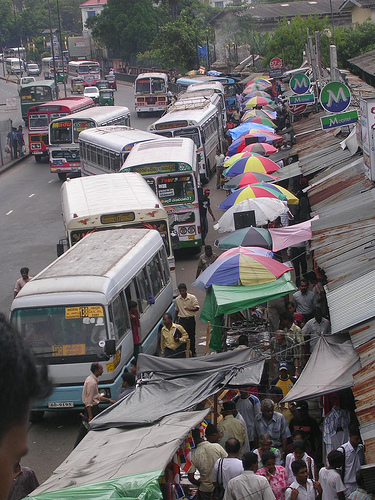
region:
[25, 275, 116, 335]
bus on a street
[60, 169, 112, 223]
bus on a street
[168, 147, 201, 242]
bus on a street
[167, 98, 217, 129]
bus on a street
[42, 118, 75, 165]
bus on a street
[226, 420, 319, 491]
people on a street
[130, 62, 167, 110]
bus on a street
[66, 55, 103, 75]
bus on a street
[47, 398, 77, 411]
plate on a bus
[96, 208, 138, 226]
sign on a bus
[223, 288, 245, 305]
the tarp is green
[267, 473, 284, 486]
the shirt is pink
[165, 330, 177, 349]
the shirt is yellow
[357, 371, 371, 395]
the roof is rusty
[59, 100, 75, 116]
the bus is red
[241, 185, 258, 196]
the umbrella is multi color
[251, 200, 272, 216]
the umbrella is white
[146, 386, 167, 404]
the tarp is gray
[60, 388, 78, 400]
the bumper is blue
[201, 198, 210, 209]
the shirt is black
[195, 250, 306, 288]
This is an umbrella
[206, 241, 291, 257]
This is an umbrella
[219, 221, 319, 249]
This is an umbrella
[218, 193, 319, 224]
This is an umbrella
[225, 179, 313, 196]
This is an umbrella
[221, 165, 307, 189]
This is an umbrella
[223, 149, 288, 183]
This is an umbrella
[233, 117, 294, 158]
This is an umbrella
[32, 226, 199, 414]
This is a bus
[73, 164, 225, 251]
This is a bus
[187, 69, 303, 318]
colorful row of umbrellas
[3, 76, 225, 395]
a series of buses in the street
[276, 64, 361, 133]
two green market signs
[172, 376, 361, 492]
a group of shoppers in the market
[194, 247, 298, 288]
one rainbow umbrella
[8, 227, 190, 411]
one blue and white bus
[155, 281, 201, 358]
two men in yellow shirts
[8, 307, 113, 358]
a bus windshield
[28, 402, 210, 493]
a grey tarp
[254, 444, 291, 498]
a woman in a pink shirt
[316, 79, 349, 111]
a blue and green sign with a white "M"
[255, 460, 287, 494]
a pink shirt on a woman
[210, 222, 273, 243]
a green and black umbrella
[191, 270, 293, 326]
a green tarp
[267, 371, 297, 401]
a blue and navy shirt on a man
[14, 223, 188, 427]
a white bus on the road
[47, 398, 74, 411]
a license plate on a bus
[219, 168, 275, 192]
a black and red umbrella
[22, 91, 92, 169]
a red bus on the road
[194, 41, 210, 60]
a blue banner next to a road